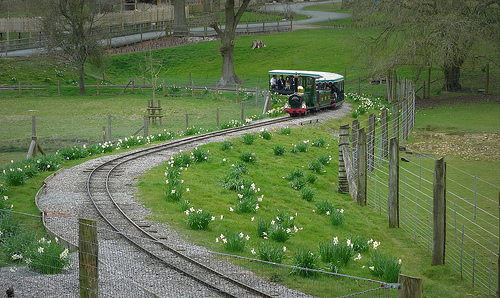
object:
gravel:
[128, 263, 133, 267]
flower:
[332, 236, 339, 245]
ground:
[0, 0, 499, 298]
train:
[267, 69, 343, 116]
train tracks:
[85, 116, 294, 297]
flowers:
[368, 266, 375, 272]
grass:
[286, 247, 320, 277]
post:
[386, 136, 398, 226]